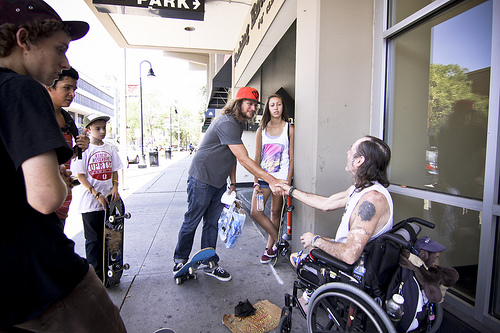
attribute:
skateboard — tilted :
[168, 244, 219, 286]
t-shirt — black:
[7, 66, 84, 270]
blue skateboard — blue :
[171, 244, 219, 283]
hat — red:
[215, 79, 272, 111]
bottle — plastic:
[250, 182, 266, 212]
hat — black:
[1, 0, 88, 50]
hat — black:
[83, 112, 108, 131]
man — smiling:
[218, 80, 264, 156]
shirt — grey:
[191, 119, 247, 195]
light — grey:
[134, 55, 156, 165]